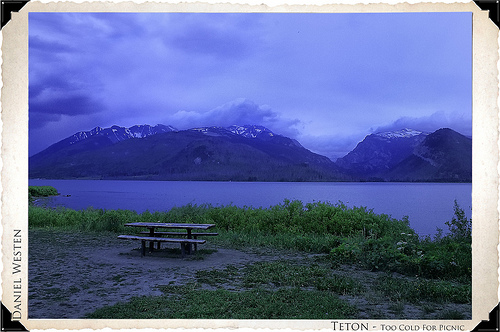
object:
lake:
[29, 167, 470, 237]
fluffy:
[77, 98, 416, 193]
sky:
[29, 11, 470, 158]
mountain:
[28, 123, 471, 179]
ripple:
[360, 181, 470, 193]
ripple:
[331, 194, 473, 205]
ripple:
[198, 184, 319, 191]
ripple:
[48, 192, 175, 207]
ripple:
[377, 202, 469, 219]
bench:
[118, 220, 216, 257]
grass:
[33, 198, 468, 318]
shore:
[32, 216, 466, 330]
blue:
[28, 12, 472, 189]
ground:
[30, 229, 468, 317]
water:
[30, 177, 472, 237]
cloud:
[28, 14, 470, 131]